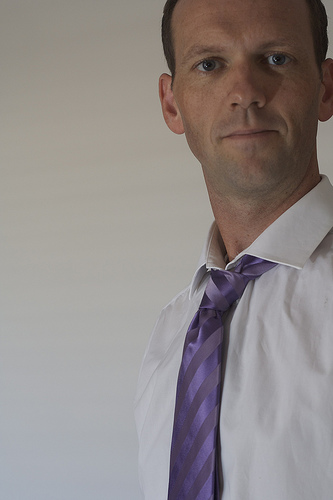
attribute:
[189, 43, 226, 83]
eye — blue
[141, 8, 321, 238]
man — wearing, turned, looking, light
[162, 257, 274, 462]
tie — purple, blue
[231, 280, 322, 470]
shirt — white, man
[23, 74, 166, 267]
wall — white, clean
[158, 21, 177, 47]
hair — black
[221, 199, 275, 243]
skin — grey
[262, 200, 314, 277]
collar — white